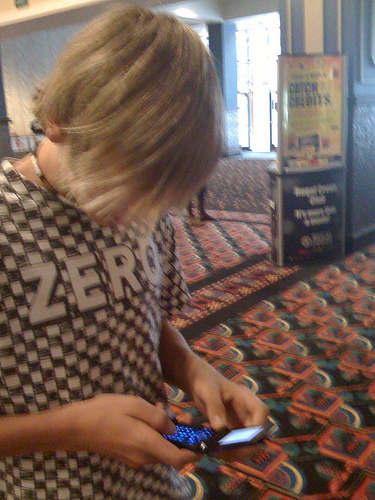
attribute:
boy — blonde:
[0, 3, 274, 499]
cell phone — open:
[156, 412, 269, 454]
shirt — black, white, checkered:
[1, 156, 190, 498]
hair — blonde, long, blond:
[33, 3, 228, 247]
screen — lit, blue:
[214, 425, 264, 446]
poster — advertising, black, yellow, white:
[276, 56, 347, 268]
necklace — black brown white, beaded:
[29, 148, 83, 209]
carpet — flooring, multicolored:
[163, 157, 374, 499]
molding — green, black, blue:
[207, 19, 245, 160]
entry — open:
[234, 12, 283, 156]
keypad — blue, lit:
[164, 420, 213, 448]